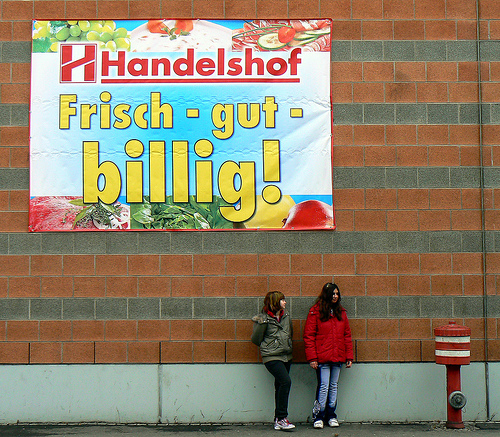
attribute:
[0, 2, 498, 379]
building — brick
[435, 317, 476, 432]
hydrant — red, white, red white, gray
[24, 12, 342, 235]
banner — german words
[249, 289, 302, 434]
girl — standing on left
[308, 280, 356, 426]
girl — standing on right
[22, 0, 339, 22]
brick — gray, concrete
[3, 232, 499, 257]
gray bricks — in row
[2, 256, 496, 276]
bricks — in a row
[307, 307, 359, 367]
jacket — red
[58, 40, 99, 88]
hogo — handelshof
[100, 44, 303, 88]
company name — underlined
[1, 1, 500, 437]
photo — during the day